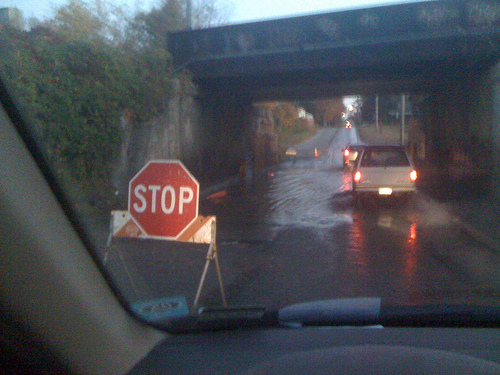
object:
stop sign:
[125, 159, 201, 241]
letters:
[133, 185, 194, 217]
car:
[350, 145, 418, 202]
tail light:
[410, 169, 418, 183]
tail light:
[352, 170, 360, 184]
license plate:
[378, 186, 393, 195]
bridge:
[166, 0, 499, 99]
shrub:
[0, 0, 201, 217]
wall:
[39, 75, 287, 209]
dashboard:
[112, 325, 499, 373]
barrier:
[104, 211, 229, 311]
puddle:
[213, 168, 461, 226]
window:
[0, 1, 499, 330]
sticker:
[129, 293, 189, 325]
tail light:
[344, 148, 351, 157]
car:
[343, 143, 369, 167]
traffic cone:
[315, 147, 319, 158]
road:
[88, 124, 500, 308]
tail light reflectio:
[408, 221, 418, 239]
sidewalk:
[416, 168, 500, 243]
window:
[361, 146, 409, 169]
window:
[348, 145, 363, 153]